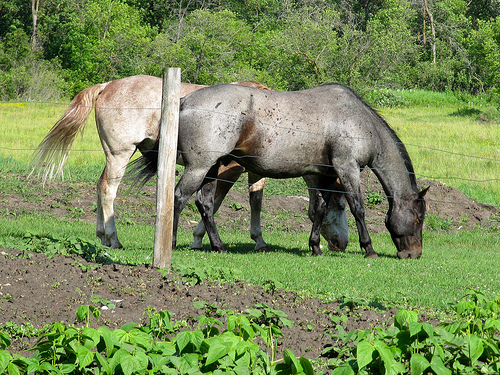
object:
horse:
[118, 81, 433, 260]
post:
[151, 67, 181, 270]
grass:
[0, 97, 500, 321]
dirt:
[0, 166, 499, 231]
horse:
[28, 74, 350, 258]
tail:
[27, 82, 110, 188]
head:
[384, 185, 432, 260]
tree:
[160, 8, 254, 84]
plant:
[181, 266, 204, 287]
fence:
[0, 67, 499, 271]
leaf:
[103, 51, 107, 56]